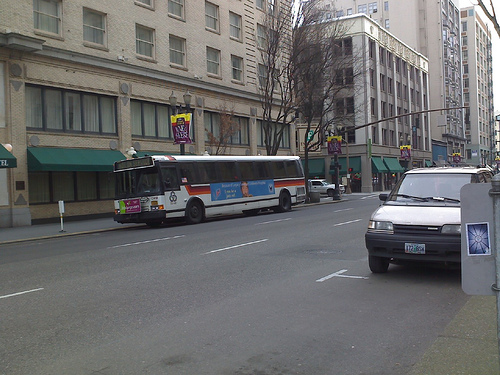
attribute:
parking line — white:
[313, 262, 368, 289]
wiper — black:
[420, 194, 460, 205]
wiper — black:
[381, 190, 422, 202]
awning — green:
[31, 147, 128, 171]